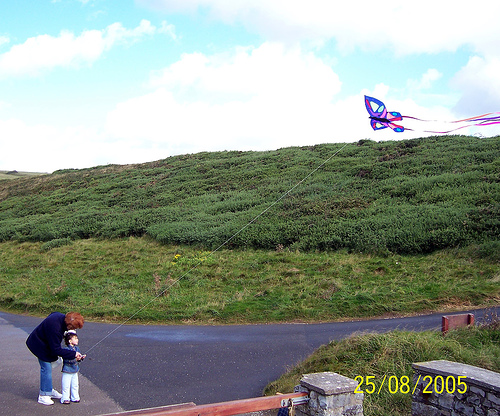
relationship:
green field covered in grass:
[0, 137, 500, 252] [93, 173, 426, 279]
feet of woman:
[34, 388, 69, 409] [23, 307, 86, 407]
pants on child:
[53, 373, 83, 407] [55, 331, 89, 405]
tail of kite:
[404, 113, 499, 135] [363, 95, 406, 132]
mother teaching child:
[26, 301, 86, 406] [61, 330, 87, 404]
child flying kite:
[61, 330, 87, 404] [360, 93, 414, 158]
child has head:
[40, 302, 109, 404] [69, 312, 88, 333]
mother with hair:
[24, 311, 82, 405] [65, 306, 84, 330]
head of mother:
[65, 312, 84, 327] [24, 311, 82, 405]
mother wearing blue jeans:
[24, 311, 82, 405] [32, 358, 57, 395]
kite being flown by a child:
[364, 94, 500, 135] [60, 332, 86, 403]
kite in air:
[361, 93, 496, 138] [12, 3, 485, 132]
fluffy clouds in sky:
[0, 0, 499, 103] [0, 0, 498, 175]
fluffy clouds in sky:
[144, 38, 343, 103] [0, 0, 498, 175]